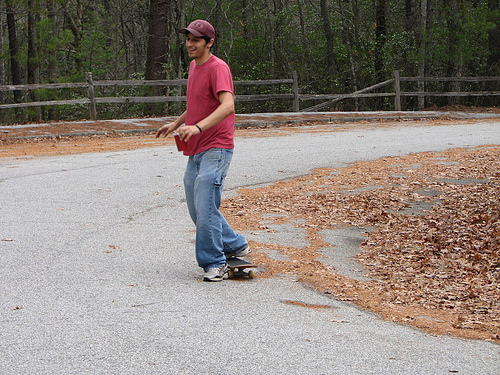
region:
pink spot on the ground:
[276, 289, 346, 319]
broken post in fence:
[288, 71, 405, 127]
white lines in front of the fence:
[23, 108, 140, 129]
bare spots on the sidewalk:
[313, 227, 378, 274]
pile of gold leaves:
[412, 240, 471, 284]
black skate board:
[212, 245, 267, 285]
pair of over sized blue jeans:
[165, 150, 253, 262]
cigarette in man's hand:
[160, 125, 197, 142]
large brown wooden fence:
[20, 62, 162, 119]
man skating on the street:
[125, 15, 267, 301]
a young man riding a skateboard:
[172, 11, 260, 302]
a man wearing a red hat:
[182, 14, 229, 56]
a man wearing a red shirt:
[163, 53, 225, 166]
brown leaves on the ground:
[321, 156, 448, 301]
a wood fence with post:
[0, 74, 157, 129]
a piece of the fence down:
[293, 65, 409, 112]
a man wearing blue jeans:
[158, 154, 237, 266]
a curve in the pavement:
[203, 129, 453, 374]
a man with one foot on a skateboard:
[207, 219, 268, 296]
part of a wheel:
[236, 258, 252, 287]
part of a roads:
[186, 333, 218, 365]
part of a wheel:
[239, 263, 259, 303]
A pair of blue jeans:
[180, 147, 252, 269]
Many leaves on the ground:
[226, 149, 498, 345]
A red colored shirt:
[169, 54, 238, 158]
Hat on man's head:
[178, 15, 219, 62]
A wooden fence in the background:
[1, 63, 498, 122]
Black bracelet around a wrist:
[190, 117, 209, 139]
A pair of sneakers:
[201, 238, 256, 286]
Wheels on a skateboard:
[223, 265, 258, 283]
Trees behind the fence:
[1, 1, 498, 117]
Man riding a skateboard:
[149, 14, 263, 289]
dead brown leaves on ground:
[219, 146, 499, 340]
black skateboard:
[225, 253, 257, 279]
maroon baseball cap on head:
[177, 17, 215, 41]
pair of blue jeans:
[182, 145, 248, 270]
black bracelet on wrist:
[192, 120, 203, 133]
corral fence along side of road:
[2, 71, 498, 126]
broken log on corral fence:
[296, 75, 395, 112]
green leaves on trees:
[7, 0, 494, 109]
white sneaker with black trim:
[201, 262, 231, 283]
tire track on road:
[2, 162, 133, 184]